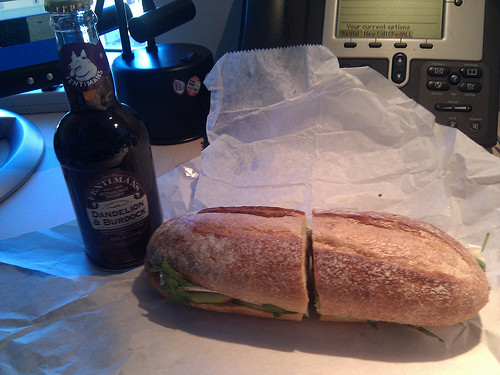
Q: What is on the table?
A: A sandwich.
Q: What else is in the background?
A: A beer.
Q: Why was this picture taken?
A: For a magazine.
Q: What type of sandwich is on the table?
A: A submarine.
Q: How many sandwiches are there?
A: One.